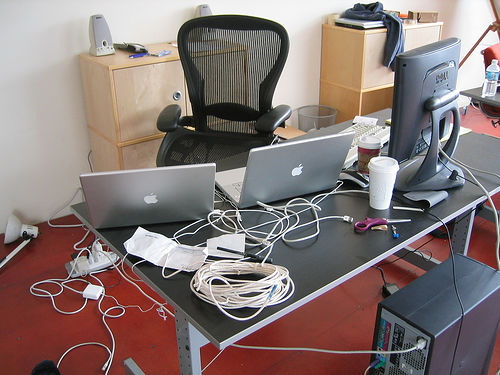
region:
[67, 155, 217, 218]
back of silver laptop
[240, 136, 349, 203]
back of silver laptop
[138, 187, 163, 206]
a logo of a bitten apple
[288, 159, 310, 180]
a logo of a bitten apple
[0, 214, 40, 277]
lamp is set down on floor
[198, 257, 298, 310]
white cord wound up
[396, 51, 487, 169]
back of black computer monitor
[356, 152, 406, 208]
white coffee cup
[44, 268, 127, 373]
white electrical cord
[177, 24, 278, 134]
chair with mesh backing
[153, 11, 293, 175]
black desk chair with mesh back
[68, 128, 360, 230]
two laptops on desk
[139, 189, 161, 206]
Apple brand logo on computer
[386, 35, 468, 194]
computer screen for desktop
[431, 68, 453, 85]
Dell brand name of desktop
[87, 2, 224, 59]
gray computer speakers on cubicle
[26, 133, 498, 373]
whole bunch of wires hooked up to electronics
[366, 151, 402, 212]
white disposable coffee cup with lid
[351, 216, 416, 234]
pair of scissors with purple handle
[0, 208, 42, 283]
white lamp laying sideways on floor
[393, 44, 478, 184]
A gray computer monitor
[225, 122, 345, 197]
A gray laptop on table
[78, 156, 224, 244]
A gray laptop on table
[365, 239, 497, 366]
A gray computer box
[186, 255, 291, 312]
A roll of white wire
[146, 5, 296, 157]
A black mesh chair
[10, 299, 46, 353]
A red floor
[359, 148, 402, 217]
A white styrofoam cup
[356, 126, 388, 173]
A brown coffee cup with a white top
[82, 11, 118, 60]
A gray computer speaker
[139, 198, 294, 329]
white wires on the table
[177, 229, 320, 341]
white wires on the table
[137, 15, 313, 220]
the chair is empty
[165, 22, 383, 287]
the chair is empty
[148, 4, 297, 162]
black chair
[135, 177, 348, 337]
white cords on the black desk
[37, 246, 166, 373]
white cords on the floor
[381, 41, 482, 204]
black monitor of the computer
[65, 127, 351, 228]
two silver laptops on the desk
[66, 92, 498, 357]
black and gray desk computers are on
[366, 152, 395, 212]
white cup with lid on the desk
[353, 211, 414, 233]
scissors with purple handles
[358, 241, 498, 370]
blue cpu on the floor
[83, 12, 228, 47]
two computer speakers